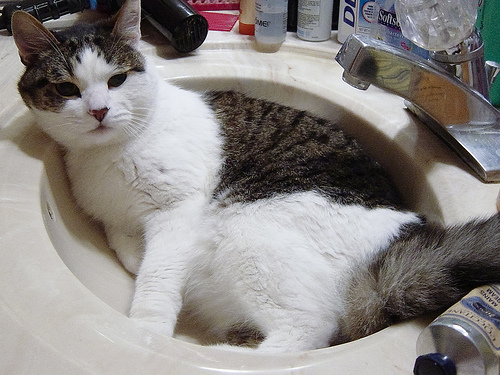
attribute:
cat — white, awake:
[8, 7, 388, 241]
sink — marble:
[37, 124, 416, 244]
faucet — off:
[332, 12, 498, 172]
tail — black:
[431, 211, 497, 283]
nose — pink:
[90, 107, 109, 121]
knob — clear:
[425, 28, 490, 64]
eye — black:
[106, 70, 127, 90]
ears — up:
[110, 5, 148, 41]